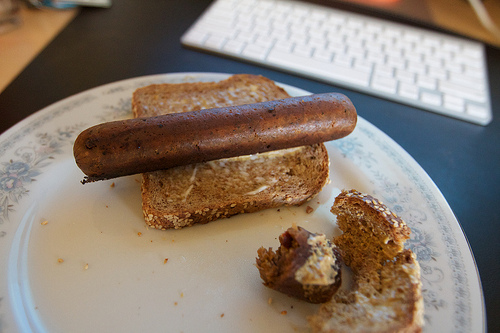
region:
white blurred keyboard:
[198, 12, 455, 114]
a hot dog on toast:
[65, 73, 367, 234]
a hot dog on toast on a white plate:
[58, 52, 476, 326]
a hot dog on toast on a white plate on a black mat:
[8, 16, 498, 328]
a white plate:
[28, 75, 495, 325]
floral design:
[27, 129, 77, 196]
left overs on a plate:
[270, 182, 421, 332]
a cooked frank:
[33, 89, 386, 208]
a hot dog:
[76, 80, 384, 216]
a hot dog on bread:
[81, 76, 374, 227]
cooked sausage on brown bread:
[70, 70, 389, 190]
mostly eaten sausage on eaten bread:
[250, 190, 387, 308]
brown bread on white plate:
[88, 86, 387, 236]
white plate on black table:
[39, 75, 401, 331]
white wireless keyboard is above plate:
[203, 20, 488, 129]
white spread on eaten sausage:
[295, 214, 334, 306]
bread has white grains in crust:
[133, 167, 311, 247]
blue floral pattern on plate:
[0, 97, 98, 230]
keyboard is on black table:
[151, 0, 498, 115]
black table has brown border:
[5, 15, 462, 331]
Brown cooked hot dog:
[65, 87, 363, 182]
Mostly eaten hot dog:
[249, 222, 349, 304]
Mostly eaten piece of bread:
[325, 183, 432, 330]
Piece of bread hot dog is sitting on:
[122, 76, 340, 228]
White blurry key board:
[172, 0, 496, 130]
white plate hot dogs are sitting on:
[0, 63, 496, 329]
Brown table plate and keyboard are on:
[10, 1, 490, 326]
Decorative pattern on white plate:
[0, 114, 77, 221]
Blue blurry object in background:
[21, 0, 128, 23]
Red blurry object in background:
[356, 0, 420, 13]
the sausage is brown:
[101, 85, 363, 186]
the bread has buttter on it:
[269, 225, 436, 320]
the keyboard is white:
[204, 12, 499, 109]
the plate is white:
[14, 213, 226, 331]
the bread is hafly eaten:
[287, 188, 434, 328]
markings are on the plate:
[388, 167, 450, 244]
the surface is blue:
[425, 132, 470, 203]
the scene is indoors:
[1, 8, 498, 318]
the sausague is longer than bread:
[65, 90, 362, 181]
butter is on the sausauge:
[265, 221, 352, 300]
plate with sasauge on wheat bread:
[10, 68, 492, 330]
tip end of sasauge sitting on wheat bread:
[72, 123, 129, 175]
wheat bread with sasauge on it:
[144, 173, 219, 228]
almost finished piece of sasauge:
[255, 223, 344, 300]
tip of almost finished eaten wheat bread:
[334, 189, 405, 246]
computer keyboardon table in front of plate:
[175, 0, 496, 124]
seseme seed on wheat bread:
[203, 207, 209, 212]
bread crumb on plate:
[164, 256, 170, 261]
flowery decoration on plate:
[5, 136, 57, 168]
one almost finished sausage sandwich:
[265, 200, 422, 328]